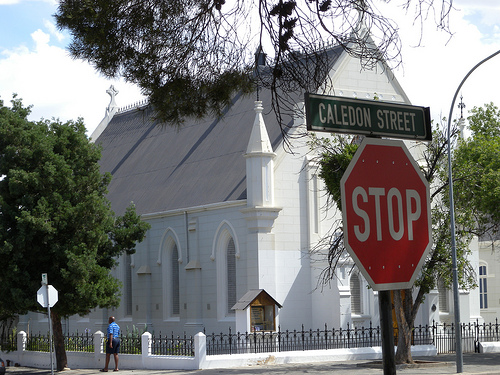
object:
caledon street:
[317, 105, 419, 127]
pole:
[380, 292, 393, 372]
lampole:
[442, 37, 499, 353]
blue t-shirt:
[107, 322, 122, 339]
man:
[99, 314, 118, 374]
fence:
[32, 297, 496, 373]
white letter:
[315, 101, 333, 128]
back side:
[34, 283, 57, 305]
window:
[223, 236, 238, 317]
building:
[20, 22, 486, 352]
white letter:
[407, 110, 420, 134]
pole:
[47, 284, 52, 374]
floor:
[165, 108, 261, 162]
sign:
[307, 94, 425, 138]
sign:
[341, 141, 433, 291]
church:
[54, 17, 447, 342]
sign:
[36, 286, 58, 308]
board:
[237, 295, 280, 334]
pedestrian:
[97, 314, 127, 365]